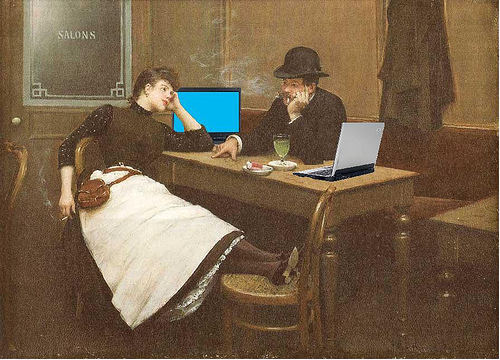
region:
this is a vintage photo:
[36, 35, 386, 270]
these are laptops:
[265, 120, 388, 195]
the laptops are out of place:
[160, 76, 423, 223]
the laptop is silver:
[293, 125, 394, 201]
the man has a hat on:
[207, 53, 358, 190]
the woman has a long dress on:
[68, 74, 282, 329]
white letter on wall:
[56, 27, 64, 43]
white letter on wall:
[63, 30, 73, 42]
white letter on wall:
[68, 29, 76, 42]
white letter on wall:
[74, 28, 81, 41]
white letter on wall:
[81, 29, 89, 41]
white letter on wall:
[87, 30, 97, 44]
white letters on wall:
[56, 30, 96, 42]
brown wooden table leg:
[321, 225, 338, 358]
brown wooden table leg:
[393, 203, 411, 358]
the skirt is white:
[69, 165, 223, 312]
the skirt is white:
[74, 169, 211, 311]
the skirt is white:
[77, 177, 209, 314]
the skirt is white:
[91, 168, 220, 322]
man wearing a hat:
[263, 48, 345, 123]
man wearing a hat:
[257, 35, 326, 113]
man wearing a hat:
[250, 31, 330, 118]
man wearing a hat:
[261, 35, 329, 119]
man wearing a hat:
[258, 35, 334, 131]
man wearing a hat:
[263, 28, 334, 128]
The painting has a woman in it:
[52, 64, 307, 329]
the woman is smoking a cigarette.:
[52, 188, 86, 220]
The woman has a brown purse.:
[75, 163, 145, 209]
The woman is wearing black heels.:
[274, 239, 319, 286]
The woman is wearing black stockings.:
[232, 234, 279, 281]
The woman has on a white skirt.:
[80, 171, 245, 303]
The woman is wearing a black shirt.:
[60, 102, 206, 187]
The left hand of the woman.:
[40, 102, 106, 214]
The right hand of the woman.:
[163, 118, 222, 155]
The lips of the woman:
[158, 98, 177, 106]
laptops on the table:
[160, 73, 380, 200]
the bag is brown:
[71, 168, 111, 203]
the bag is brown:
[55, 174, 107, 214]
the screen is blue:
[164, 76, 251, 142]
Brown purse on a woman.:
[78, 179, 110, 208]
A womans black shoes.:
[272, 241, 305, 284]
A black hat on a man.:
[270, 46, 330, 79]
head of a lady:
[96, 58, 201, 142]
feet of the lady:
[236, 225, 311, 302]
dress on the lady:
[29, 135, 253, 348]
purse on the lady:
[43, 164, 125, 239]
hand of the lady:
[44, 188, 89, 228]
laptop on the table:
[285, 112, 404, 207]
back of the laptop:
[316, 108, 401, 195]